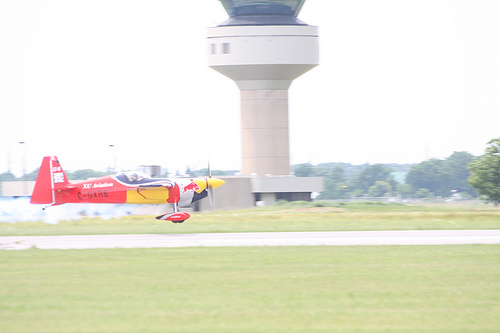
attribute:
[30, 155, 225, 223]
plane — red, yellow, small, older, single, landing, taking off, flying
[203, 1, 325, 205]
tower — round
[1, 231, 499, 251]
runway — narrow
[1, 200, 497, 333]
grass — green, short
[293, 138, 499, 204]
trees — green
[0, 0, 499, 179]
sky — showing, light, gray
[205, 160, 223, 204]
propeller — yellow